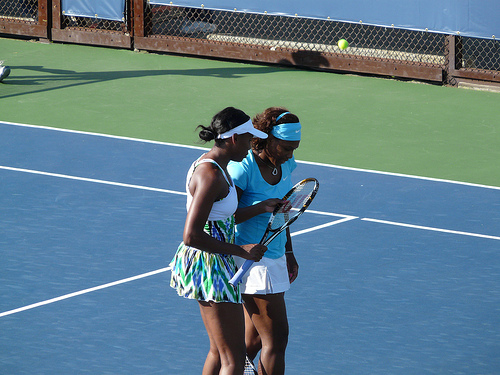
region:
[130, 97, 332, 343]
two tennis players on a court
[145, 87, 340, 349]
one player taking while other listens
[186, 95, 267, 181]
woman wearing visor with hair pulled back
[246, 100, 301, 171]
woman wearing thick and thin hair bands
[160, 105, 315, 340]
player holding racket with both hands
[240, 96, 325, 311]
player wearing blue shirt with white skirt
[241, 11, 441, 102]
yellow ball in air by fence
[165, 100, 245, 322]
woman wearing tennis dress with blue and green designs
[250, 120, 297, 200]
player wearing necklace with shiny pendant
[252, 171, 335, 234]
fingers curled under strings of racket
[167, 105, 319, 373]
Venus and Serena Williams on the tennis court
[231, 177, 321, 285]
Wilson tennis racket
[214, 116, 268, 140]
White visor on female tennis player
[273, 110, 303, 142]
Light blue Nike bandanna on female tennis player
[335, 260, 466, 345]
Blue color tennis court surface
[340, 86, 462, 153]
Green color out-of-bounds area on tennis court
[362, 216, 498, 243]
White singles line on tennis court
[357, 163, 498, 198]
White doubles out-of-bounds line on tennis court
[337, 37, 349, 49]
Yellow tennis ball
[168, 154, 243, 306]
Short-length dress on female tennis player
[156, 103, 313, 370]
two women on a tennis court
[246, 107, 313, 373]
woman in white skirt and blue top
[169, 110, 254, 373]
woman wearing white visor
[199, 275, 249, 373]
legs of woman in white visor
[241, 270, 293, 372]
legs of woman in blue top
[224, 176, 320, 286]
tennis racket of woman in white visor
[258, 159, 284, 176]
necklace of woman in blue top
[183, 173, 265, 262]
right arm of woman in white visor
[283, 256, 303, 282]
left hand of woman in blue top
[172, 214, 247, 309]
colorful skirt of woman in white visor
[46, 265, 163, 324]
broad lines on tennis court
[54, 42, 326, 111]
shadow on side of the court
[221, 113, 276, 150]
white visor on Venus Williams head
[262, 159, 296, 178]
silver necklace on Serena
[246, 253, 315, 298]
Serena Williams white skirt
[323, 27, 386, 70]
yellow tennis ball in fence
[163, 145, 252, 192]
strap on tennis dress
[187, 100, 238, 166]
black hair held up in a bun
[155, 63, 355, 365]
Serena and Venus talking on the tennis court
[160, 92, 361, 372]
The two women are playing tennis.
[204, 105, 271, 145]
The woman wears a visor.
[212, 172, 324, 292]
The woman holds a racquet.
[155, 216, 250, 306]
The woman wears a colorful skirt.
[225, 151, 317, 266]
The woman wears a blue top.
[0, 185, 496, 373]
The court is blue.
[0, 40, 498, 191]
The border of the court is green.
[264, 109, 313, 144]
The woman wears a blue headband.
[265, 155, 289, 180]
The woman wears a necklace.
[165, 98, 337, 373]
The women are African American.